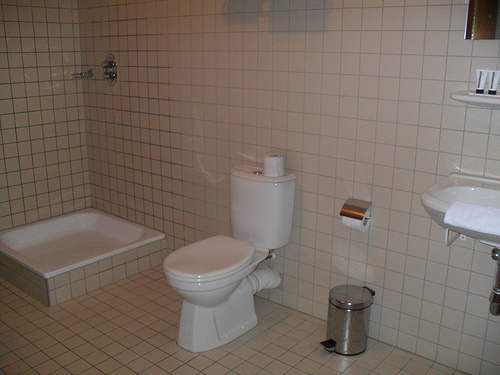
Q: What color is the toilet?
A: White.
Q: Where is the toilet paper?
A: On the toilet.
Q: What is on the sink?
A: Towels.